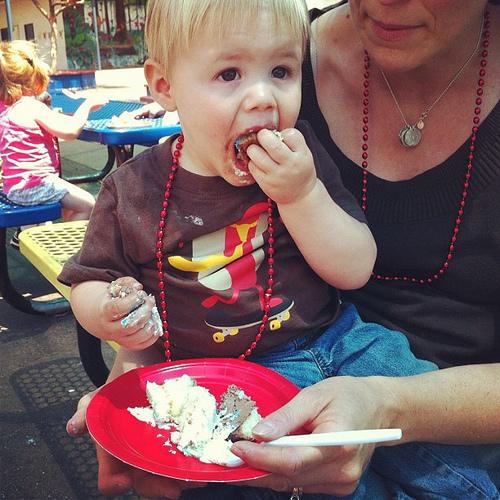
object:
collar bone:
[318, 41, 364, 97]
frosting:
[125, 372, 264, 465]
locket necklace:
[375, 15, 487, 149]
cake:
[126, 369, 271, 471]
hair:
[143, 0, 310, 79]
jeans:
[244, 304, 499, 499]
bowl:
[84, 356, 308, 483]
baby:
[57, 0, 497, 499]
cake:
[233, 125, 282, 167]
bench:
[0, 197, 72, 318]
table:
[39, 89, 184, 187]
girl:
[0, 40, 110, 248]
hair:
[0, 38, 50, 106]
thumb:
[250, 379, 326, 442]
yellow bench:
[16, 220, 120, 390]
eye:
[270, 63, 292, 82]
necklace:
[150, 125, 278, 366]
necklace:
[356, 0, 493, 288]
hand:
[96, 275, 159, 352]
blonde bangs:
[163, 0, 317, 55]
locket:
[394, 123, 419, 151]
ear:
[140, 57, 177, 113]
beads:
[470, 114, 481, 126]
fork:
[199, 426, 403, 472]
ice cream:
[105, 272, 166, 338]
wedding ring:
[286, 484, 304, 499]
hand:
[224, 374, 397, 498]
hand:
[244, 125, 318, 211]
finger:
[227, 420, 358, 477]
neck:
[393, 18, 478, 88]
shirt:
[56, 117, 370, 369]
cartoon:
[167, 199, 295, 344]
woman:
[66, 0, 499, 498]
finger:
[230, 451, 364, 493]